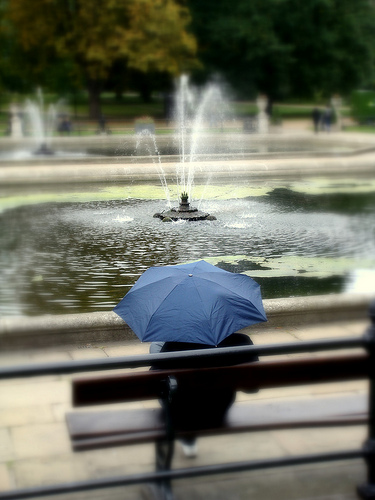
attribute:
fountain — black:
[147, 180, 223, 226]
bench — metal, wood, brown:
[50, 353, 360, 480]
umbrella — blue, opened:
[127, 258, 248, 336]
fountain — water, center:
[3, 148, 289, 284]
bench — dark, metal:
[65, 350, 369, 498]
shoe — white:
[178, 438, 201, 458]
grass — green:
[3, 88, 374, 131]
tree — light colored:
[8, 7, 207, 107]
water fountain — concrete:
[0, 155, 372, 347]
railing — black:
[1, 335, 374, 498]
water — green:
[41, 214, 343, 263]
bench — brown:
[56, 303, 373, 497]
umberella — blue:
[111, 257, 269, 348]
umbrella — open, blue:
[110, 260, 266, 346]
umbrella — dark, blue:
[101, 251, 274, 350]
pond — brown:
[7, 199, 373, 293]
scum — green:
[102, 181, 255, 200]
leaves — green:
[99, 34, 152, 81]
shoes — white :
[173, 437, 201, 458]